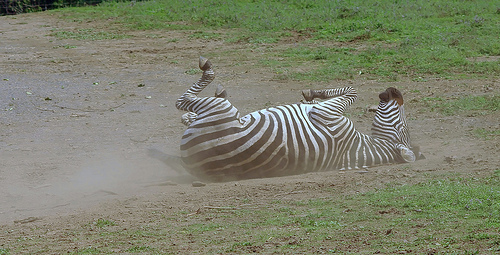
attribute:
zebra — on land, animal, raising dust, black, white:
[176, 58, 426, 181]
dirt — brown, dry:
[1, 1, 498, 254]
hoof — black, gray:
[199, 57, 213, 71]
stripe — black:
[297, 104, 327, 172]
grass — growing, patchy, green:
[37, 2, 498, 84]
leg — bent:
[314, 88, 360, 115]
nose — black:
[379, 89, 403, 105]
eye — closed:
[400, 119, 406, 127]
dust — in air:
[77, 130, 208, 197]